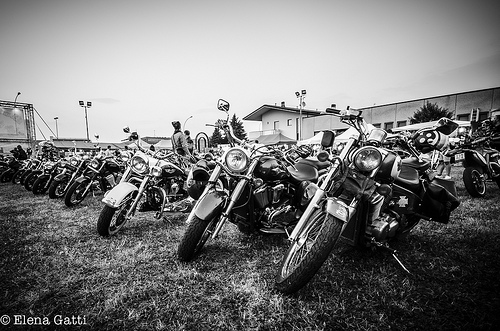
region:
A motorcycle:
[313, 100, 436, 288]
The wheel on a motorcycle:
[286, 195, 347, 302]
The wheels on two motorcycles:
[185, 180, 375, 285]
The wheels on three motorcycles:
[100, 170, 360, 290]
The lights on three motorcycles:
[117, 142, 377, 174]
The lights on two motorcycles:
[215, 140, 385, 170]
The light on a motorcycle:
[340, 145, 380, 170]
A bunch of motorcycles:
[45, 118, 470, 280]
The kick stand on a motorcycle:
[382, 226, 421, 288]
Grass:
[85, 246, 265, 318]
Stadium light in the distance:
[65, 93, 105, 133]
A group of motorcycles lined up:
[19, 95, 459, 284]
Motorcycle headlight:
[213, 142, 253, 180]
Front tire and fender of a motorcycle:
[270, 189, 347, 294]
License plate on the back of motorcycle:
[450, 149, 472, 165]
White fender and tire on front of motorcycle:
[93, 128, 187, 243]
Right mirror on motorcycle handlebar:
[213, 87, 240, 118]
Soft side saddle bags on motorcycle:
[416, 170, 463, 235]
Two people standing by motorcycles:
[159, 111, 201, 171]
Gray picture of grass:
[9, 236, 169, 310]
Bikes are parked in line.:
[0, 136, 393, 228]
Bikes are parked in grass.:
[55, 191, 220, 311]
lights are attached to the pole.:
[50, 77, 345, 130]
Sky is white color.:
[43, 12, 405, 77]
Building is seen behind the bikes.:
[257, 95, 492, 130]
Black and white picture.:
[20, 60, 480, 316]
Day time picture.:
[17, 31, 488, 312]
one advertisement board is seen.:
[2, 96, 42, 141]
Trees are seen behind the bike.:
[205, 113, 496, 140]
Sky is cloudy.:
[29, 19, 421, 85]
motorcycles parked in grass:
[17, 145, 399, 269]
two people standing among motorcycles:
[162, 114, 197, 155]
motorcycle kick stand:
[388, 238, 445, 303]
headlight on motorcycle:
[222, 150, 251, 175]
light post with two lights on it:
[70, 93, 100, 140]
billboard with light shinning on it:
[2, 91, 40, 146]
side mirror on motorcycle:
[200, 96, 235, 123]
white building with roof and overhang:
[238, 101, 359, 134]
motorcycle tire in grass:
[281, 201, 347, 302]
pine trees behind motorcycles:
[209, 107, 251, 149]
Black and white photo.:
[9, 16, 476, 324]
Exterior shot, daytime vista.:
[10, 30, 464, 308]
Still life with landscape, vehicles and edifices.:
[9, 89, 461, 301]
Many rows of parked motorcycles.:
[17, 121, 489, 292]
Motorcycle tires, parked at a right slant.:
[30, 159, 360, 284]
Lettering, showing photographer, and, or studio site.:
[7, 303, 104, 329]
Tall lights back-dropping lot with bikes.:
[41, 85, 306, 113]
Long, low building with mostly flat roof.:
[253, 85, 498, 155]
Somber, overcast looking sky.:
[38, 12, 359, 93]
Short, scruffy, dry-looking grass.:
[36, 222, 184, 317]